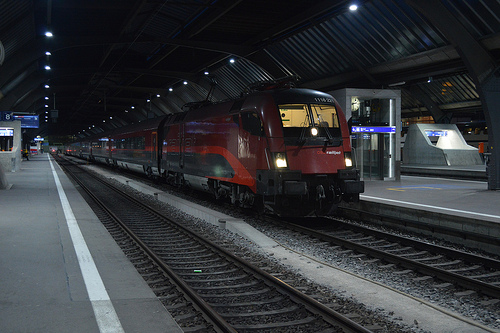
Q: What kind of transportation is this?
A: Train.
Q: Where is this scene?
A: Train station.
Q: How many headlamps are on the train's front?
A: Three.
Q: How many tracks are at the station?
A: Two.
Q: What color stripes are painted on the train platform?
A: White.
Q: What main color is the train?
A: Red.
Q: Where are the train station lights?
A: On the ceiling.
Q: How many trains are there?
A: One.